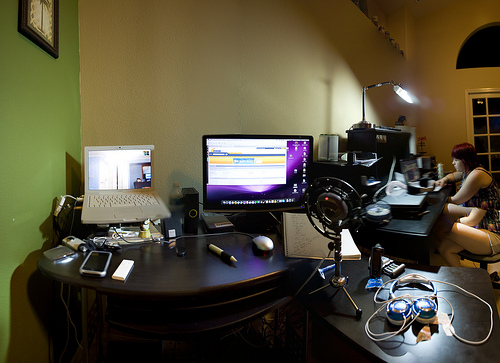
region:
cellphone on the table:
[82, 242, 110, 282]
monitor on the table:
[193, 128, 337, 219]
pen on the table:
[206, 238, 242, 263]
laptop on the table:
[71, 138, 161, 235]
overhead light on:
[355, 60, 440, 128]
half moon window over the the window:
[448, 1, 498, 83]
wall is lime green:
[3, 54, 77, 147]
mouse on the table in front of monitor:
[246, 226, 311, 272]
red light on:
[304, 185, 350, 225]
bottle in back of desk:
[161, 176, 182, 214]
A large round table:
[32, 223, 314, 312]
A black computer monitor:
[198, 125, 315, 223]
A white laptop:
[71, 135, 168, 225]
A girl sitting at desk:
[449, 140, 495, 247]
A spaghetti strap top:
[459, 167, 498, 223]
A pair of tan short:
[479, 225, 499, 252]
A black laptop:
[387, 153, 439, 197]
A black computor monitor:
[178, 181, 199, 262]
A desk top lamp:
[359, 64, 415, 115]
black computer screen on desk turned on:
[201, 134, 313, 210]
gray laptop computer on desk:
[82, 145, 170, 224]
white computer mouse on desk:
[250, 233, 273, 253]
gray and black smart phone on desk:
[78, 249, 113, 276]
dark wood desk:
[38, 220, 316, 337]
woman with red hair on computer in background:
[432, 142, 499, 267]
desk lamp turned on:
[353, 79, 415, 131]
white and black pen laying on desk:
[206, 241, 237, 263]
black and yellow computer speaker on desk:
[182, 188, 200, 237]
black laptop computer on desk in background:
[396, 158, 441, 191]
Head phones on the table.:
[385, 269, 440, 326]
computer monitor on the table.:
[200, 130, 312, 217]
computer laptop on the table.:
[77, 137, 172, 227]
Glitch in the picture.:
[427, 149, 497, 256]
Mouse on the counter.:
[249, 229, 274, 258]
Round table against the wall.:
[41, 222, 316, 345]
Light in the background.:
[357, 67, 419, 127]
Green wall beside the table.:
[0, 0, 81, 359]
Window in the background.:
[465, 87, 498, 182]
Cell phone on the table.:
[77, 243, 112, 279]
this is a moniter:
[181, 108, 339, 239]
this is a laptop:
[66, 123, 188, 245]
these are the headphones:
[368, 262, 498, 357]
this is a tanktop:
[453, 168, 498, 245]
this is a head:
[441, 140, 483, 182]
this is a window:
[456, 78, 498, 182]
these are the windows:
[464, 85, 499, 183]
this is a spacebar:
[106, 196, 138, 214]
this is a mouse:
[243, 224, 290, 265]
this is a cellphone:
[75, 241, 119, 283]